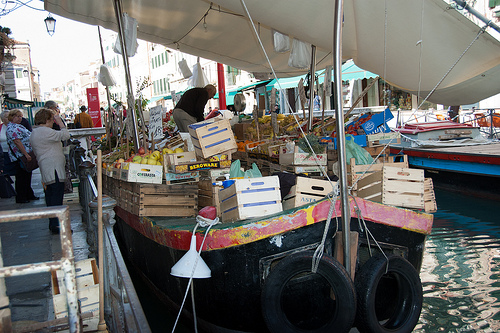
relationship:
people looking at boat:
[31, 109, 77, 235] [81, 133, 434, 330]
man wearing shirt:
[172, 84, 217, 133] [175, 86, 208, 117]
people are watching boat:
[7, 93, 77, 208] [81, 133, 434, 330]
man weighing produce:
[178, 77, 217, 127] [139, 111, 354, 161]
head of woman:
[35, 108, 55, 129] [24, 88, 104, 238]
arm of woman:
[37, 104, 67, 142] [28, 105, 90, 234]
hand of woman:
[26, 159, 36, 175] [10, 108, 50, 178]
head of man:
[188, 80, 227, 101] [162, 73, 231, 145]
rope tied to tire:
[305, 180, 354, 237] [245, 236, 409, 329]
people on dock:
[31, 109, 77, 235] [15, 177, 134, 312]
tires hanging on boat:
[269, 230, 432, 330] [109, 179, 431, 282]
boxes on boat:
[148, 124, 309, 206] [116, 135, 400, 315]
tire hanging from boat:
[355, 250, 425, 331] [42, 0, 483, 330]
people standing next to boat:
[31, 109, 77, 235] [42, 0, 483, 330]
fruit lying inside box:
[146, 159, 156, 165] [117, 160, 163, 186]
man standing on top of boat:
[172, 84, 217, 133] [42, 0, 483, 330]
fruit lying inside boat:
[146, 159, 156, 165] [42, 0, 483, 330]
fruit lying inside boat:
[250, 143, 255, 148] [42, 0, 483, 330]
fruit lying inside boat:
[285, 116, 305, 136] [42, 0, 483, 330]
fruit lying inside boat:
[258, 110, 288, 122] [42, 0, 483, 330]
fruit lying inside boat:
[119, 147, 166, 168] [42, 0, 483, 330]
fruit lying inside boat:
[106, 145, 155, 165] [42, 0, 483, 330]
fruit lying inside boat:
[233, 135, 265, 151] [42, 0, 483, 330]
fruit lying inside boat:
[282, 115, 313, 131] [42, 0, 483, 330]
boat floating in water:
[42, 0, 483, 330] [409, 187, 484, 330]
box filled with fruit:
[116, 160, 165, 183] [250, 143, 255, 148]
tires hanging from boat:
[263, 251, 358, 332] [42, 0, 483, 330]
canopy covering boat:
[42, 1, 484, 108] [42, 0, 483, 330]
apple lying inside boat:
[146, 151, 160, 161] [42, 0, 483, 330]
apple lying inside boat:
[131, 155, 141, 162] [42, 0, 483, 330]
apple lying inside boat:
[173, 146, 184, 155] [42, 0, 483, 330]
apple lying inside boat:
[135, 146, 146, 155] [42, 0, 483, 330]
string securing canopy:
[344, 19, 484, 193] [42, 1, 484, 108]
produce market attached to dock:
[88, 95, 441, 217] [2, 131, 155, 331]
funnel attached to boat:
[169, 235, 213, 280] [42, 0, 483, 330]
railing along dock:
[74, 137, 158, 329] [10, 158, 123, 330]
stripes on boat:
[398, 155, 498, 179] [365, 119, 498, 230]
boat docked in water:
[42, 0, 500, 332] [424, 212, 499, 322]